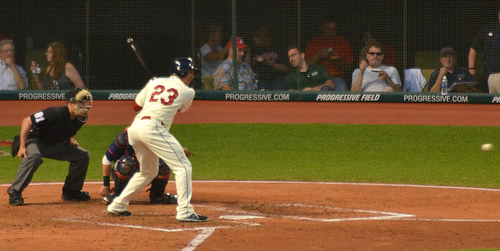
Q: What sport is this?
A: Baseball.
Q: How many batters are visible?
A: One.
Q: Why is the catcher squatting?
A: To catch the ball.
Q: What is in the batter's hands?
A: A bat.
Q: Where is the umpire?
A: Behind the catcher.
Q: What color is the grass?
A: Green.